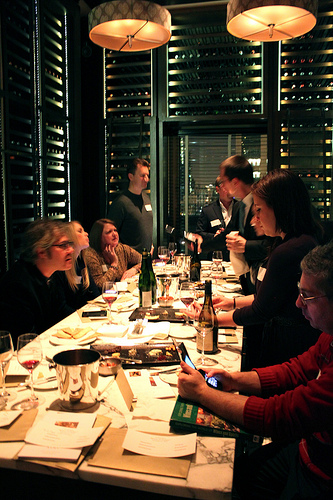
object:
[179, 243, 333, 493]
man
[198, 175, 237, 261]
man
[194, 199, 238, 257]
blazer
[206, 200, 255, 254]
blazer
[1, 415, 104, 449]
papers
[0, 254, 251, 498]
table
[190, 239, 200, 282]
bottle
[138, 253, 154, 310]
bottle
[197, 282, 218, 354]
bottle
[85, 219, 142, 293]
lady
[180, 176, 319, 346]
lady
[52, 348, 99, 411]
bucket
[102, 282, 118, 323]
glass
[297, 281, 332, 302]
glasses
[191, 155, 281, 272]
man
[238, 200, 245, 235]
tie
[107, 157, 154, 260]
man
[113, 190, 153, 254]
sweater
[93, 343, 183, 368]
plate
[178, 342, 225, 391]
phone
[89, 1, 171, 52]
lights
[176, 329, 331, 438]
arms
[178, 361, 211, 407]
hands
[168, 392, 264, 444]
book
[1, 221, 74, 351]
man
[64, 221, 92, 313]
woman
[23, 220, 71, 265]
hair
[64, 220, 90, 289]
hair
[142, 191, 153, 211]
name tag